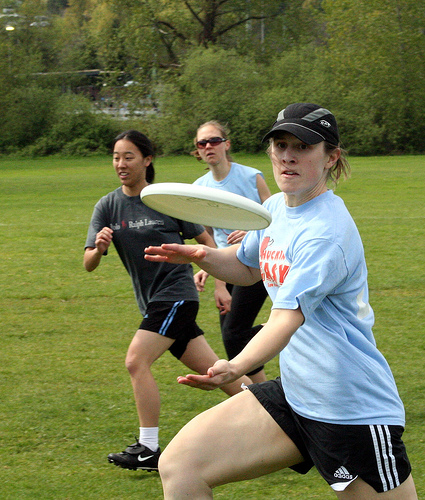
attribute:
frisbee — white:
[138, 181, 274, 235]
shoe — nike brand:
[109, 435, 160, 472]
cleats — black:
[106, 439, 164, 483]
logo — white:
[135, 449, 155, 464]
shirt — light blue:
[222, 193, 414, 406]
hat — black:
[265, 84, 368, 153]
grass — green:
[0, 156, 424, 499]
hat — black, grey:
[260, 100, 340, 143]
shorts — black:
[138, 300, 204, 359]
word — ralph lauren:
[127, 214, 168, 227]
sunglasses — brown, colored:
[194, 135, 228, 148]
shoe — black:
[101, 414, 170, 471]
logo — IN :
[329, 459, 353, 485]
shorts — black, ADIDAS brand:
[238, 373, 412, 494]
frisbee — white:
[151, 168, 371, 268]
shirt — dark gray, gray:
[83, 184, 205, 316]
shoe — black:
[104, 439, 165, 473]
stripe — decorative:
[370, 421, 405, 489]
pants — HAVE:
[254, 379, 409, 494]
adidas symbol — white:
[328, 461, 357, 482]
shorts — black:
[251, 365, 408, 496]